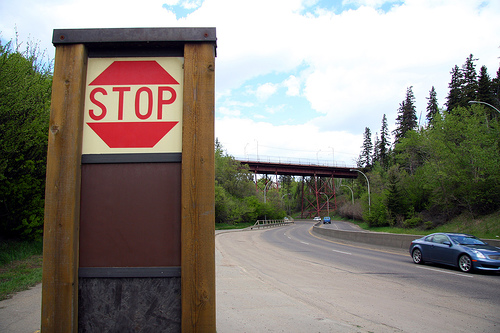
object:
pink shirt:
[408, 231, 500, 273]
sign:
[80, 57, 183, 155]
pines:
[368, 99, 498, 229]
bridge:
[235, 159, 365, 219]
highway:
[218, 216, 498, 331]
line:
[333, 250, 352, 256]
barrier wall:
[312, 219, 500, 250]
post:
[179, 42, 214, 332]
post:
[39, 45, 82, 331]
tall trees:
[425, 86, 440, 128]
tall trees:
[377, 113, 391, 164]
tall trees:
[359, 127, 372, 166]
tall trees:
[391, 85, 418, 138]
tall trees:
[443, 64, 464, 111]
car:
[409, 232, 500, 274]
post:
[349, 169, 371, 215]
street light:
[349, 168, 371, 216]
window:
[449, 235, 485, 244]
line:
[327, 245, 354, 257]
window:
[432, 234, 450, 244]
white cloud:
[0, 0, 499, 160]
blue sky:
[0, 0, 500, 154]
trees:
[463, 53, 479, 106]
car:
[313, 217, 321, 222]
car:
[323, 217, 331, 224]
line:
[411, 260, 474, 280]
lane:
[320, 220, 394, 232]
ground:
[4, 216, 498, 330]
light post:
[349, 169, 371, 213]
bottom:
[74, 264, 182, 333]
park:
[0, 34, 498, 283]